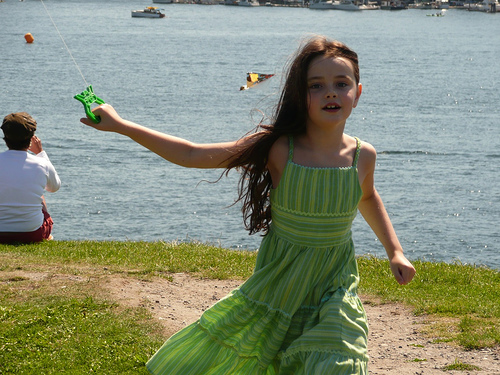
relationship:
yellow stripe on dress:
[335, 168, 343, 213] [242, 156, 362, 368]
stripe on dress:
[317, 169, 355, 208] [144, 134, 370, 373]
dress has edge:
[143, 135, 370, 375] [201, 297, 231, 323]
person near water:
[0, 111, 57, 242] [3, 2, 498, 265]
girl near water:
[80, 31, 415, 373] [120, 51, 237, 121]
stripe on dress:
[317, 169, 355, 208] [126, 119, 418, 372]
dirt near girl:
[0, 258, 500, 373] [80, 31, 415, 373]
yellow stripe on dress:
[338, 171, 342, 213] [209, 165, 370, 374]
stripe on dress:
[326, 169, 351, 208] [153, 145, 383, 372]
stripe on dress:
[317, 169, 355, 208] [155, 122, 387, 372]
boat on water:
[102, 3, 179, 33] [34, 8, 491, 246]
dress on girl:
[143, 129, 393, 374] [80, 31, 415, 373]